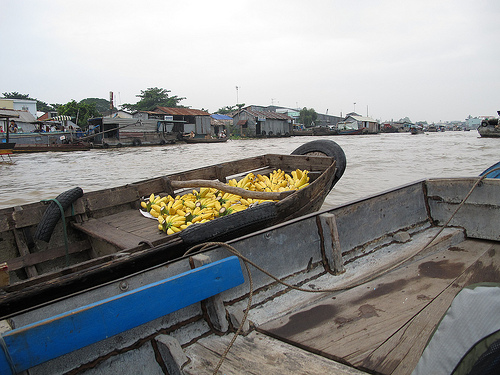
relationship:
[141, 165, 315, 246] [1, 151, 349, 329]
bananas on a boat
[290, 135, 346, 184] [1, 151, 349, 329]
tire on boat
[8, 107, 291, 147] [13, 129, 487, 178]
houses are by river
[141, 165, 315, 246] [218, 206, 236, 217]
bananas have tops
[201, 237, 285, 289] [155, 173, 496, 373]
wires are in boat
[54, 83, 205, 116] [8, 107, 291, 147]
trees are behind houses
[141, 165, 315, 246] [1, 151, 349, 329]
bananas are on boat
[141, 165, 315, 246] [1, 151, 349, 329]
bananas are in boat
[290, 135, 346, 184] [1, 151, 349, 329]
tire attached to boat